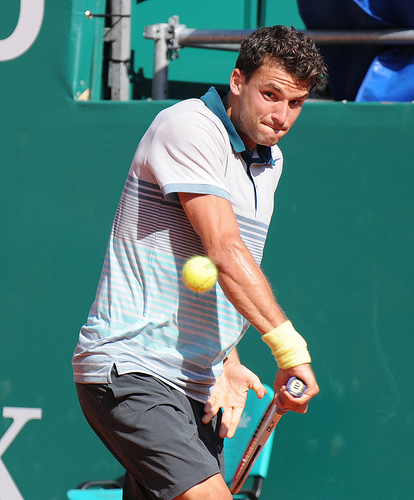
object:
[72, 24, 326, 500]
man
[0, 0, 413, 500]
wall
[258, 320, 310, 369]
wristband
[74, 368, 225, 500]
shorts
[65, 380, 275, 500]
chair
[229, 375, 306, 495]
racket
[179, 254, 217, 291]
ball